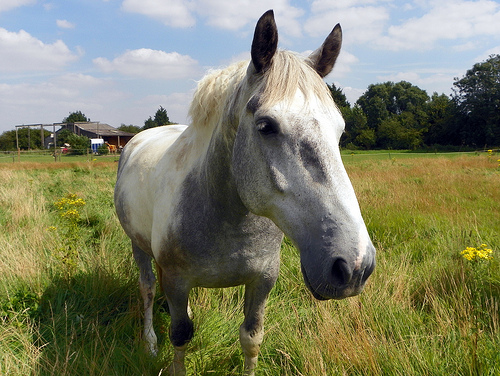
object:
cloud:
[91, 47, 201, 83]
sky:
[0, 0, 500, 135]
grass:
[0, 149, 500, 376]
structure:
[12, 121, 103, 152]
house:
[72, 121, 136, 149]